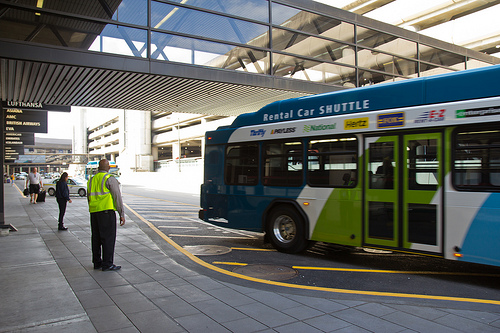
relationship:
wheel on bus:
[263, 197, 311, 254] [172, 63, 497, 268]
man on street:
[84, 153, 129, 270] [0, 261, 499, 332]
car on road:
[39, 175, 92, 196] [0, 261, 499, 332]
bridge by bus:
[2, 5, 499, 115] [172, 63, 497, 268]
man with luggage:
[25, 165, 39, 206] [22, 187, 48, 203]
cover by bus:
[177, 243, 230, 257] [172, 63, 497, 268]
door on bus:
[366, 134, 444, 252] [172, 63, 497, 268]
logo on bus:
[250, 129, 271, 138] [172, 63, 497, 268]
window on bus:
[305, 136, 358, 188] [172, 63, 497, 268]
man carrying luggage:
[25, 165, 39, 206] [22, 187, 48, 203]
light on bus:
[301, 198, 312, 210] [172, 63, 497, 268]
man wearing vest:
[84, 153, 129, 270] [82, 171, 122, 216]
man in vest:
[84, 153, 129, 270] [82, 171, 122, 216]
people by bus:
[24, 157, 135, 270] [172, 63, 497, 268]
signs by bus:
[0, 99, 51, 163] [172, 63, 497, 268]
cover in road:
[177, 243, 230, 257] [0, 261, 499, 332]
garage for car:
[76, 0, 492, 171] [39, 175, 92, 196]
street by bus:
[0, 261, 499, 332] [172, 63, 497, 268]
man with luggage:
[84, 153, 129, 270] [22, 187, 48, 203]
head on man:
[96, 158, 113, 173] [84, 153, 129, 270]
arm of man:
[107, 175, 129, 227] [84, 153, 129, 270]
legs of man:
[87, 212, 128, 272] [84, 153, 129, 270]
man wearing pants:
[84, 153, 129, 270] [87, 212, 128, 272]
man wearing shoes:
[84, 153, 129, 270] [89, 261, 125, 275]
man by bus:
[84, 153, 129, 270] [172, 63, 497, 268]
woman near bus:
[54, 170, 76, 231] [172, 63, 497, 268]